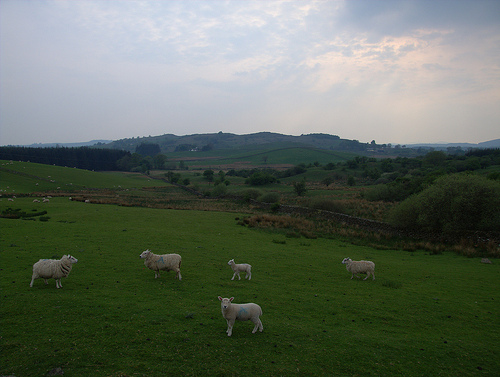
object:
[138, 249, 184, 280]
sheep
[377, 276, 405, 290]
bush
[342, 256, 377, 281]
sheep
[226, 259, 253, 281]
sheep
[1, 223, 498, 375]
field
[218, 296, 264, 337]
sheep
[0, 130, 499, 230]
trees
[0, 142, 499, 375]
grass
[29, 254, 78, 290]
sheep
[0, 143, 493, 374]
field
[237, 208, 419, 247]
bush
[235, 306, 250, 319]
marked